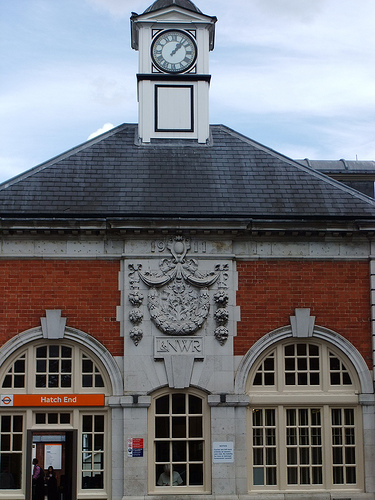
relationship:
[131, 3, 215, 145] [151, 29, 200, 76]
tower has clock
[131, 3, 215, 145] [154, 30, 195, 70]
tower has face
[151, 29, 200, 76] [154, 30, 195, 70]
clock has face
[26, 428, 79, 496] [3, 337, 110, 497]
entryway surrounded by windows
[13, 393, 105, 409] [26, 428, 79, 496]
sign above entryway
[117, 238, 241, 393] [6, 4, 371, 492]
sculpture on face of building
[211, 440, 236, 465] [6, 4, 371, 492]
sign on face of building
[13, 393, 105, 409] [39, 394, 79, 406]
sign states "hatch end"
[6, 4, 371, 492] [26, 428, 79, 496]
building has entryway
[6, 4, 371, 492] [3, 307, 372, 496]
building has windows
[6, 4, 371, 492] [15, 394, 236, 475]
building has signs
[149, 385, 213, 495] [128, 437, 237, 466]
window has signs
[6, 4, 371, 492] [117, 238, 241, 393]
building has sculpture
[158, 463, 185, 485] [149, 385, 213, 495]
person behind window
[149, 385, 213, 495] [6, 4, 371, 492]
window in center of building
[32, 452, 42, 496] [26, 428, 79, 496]
person standing in entryway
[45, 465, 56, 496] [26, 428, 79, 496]
person standing in entryway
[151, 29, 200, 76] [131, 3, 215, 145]
clock on tower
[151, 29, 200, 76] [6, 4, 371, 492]
clock on building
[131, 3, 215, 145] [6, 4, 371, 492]
tower on top of building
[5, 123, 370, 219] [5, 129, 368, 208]
roof has shingles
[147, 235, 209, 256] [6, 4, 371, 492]
1911 carved into building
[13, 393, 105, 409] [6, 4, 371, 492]
sign on face of building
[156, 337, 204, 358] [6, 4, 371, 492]
sign on face of building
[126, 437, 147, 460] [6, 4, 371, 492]
sign on face of building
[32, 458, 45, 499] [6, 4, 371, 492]
person are inside building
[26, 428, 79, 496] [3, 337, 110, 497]
entryway in middle of windows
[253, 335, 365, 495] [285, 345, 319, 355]
window has panes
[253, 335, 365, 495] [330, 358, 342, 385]
window has panes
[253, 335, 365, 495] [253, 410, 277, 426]
window has panes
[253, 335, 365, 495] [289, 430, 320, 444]
window has panes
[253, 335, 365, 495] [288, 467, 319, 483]
window has panes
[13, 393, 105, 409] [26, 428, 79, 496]
sign over entryway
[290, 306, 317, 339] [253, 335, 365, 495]
stone above window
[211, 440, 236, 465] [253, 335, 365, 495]
sign next to window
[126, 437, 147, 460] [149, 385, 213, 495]
sign next to window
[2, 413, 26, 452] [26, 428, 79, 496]
window by entryway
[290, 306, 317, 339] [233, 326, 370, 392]
stone on top of arch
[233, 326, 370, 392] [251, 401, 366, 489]
arch on top of window